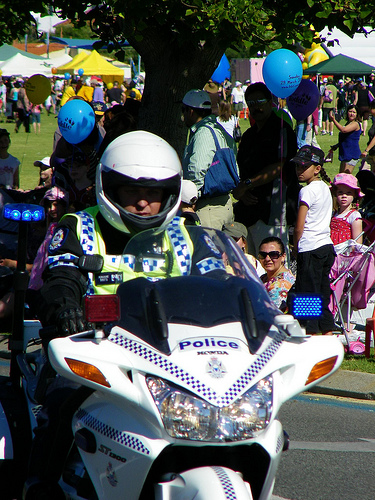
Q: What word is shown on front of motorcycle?
A: Police.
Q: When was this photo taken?
A: Daytime.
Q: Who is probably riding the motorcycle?
A: Policeman.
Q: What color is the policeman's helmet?
A: White.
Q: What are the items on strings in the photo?
A: Balloons.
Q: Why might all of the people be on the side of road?
A: At parade.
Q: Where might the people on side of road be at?
A: In park.